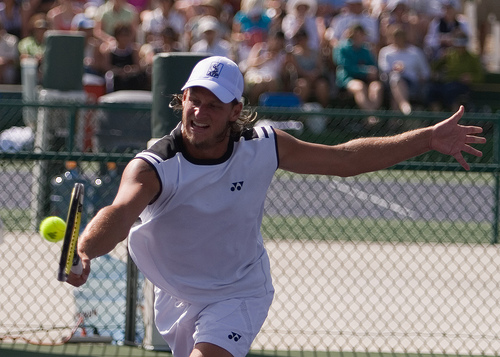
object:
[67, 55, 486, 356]
man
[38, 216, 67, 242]
ball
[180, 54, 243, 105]
cap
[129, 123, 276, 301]
shirt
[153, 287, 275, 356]
shorts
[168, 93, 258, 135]
hair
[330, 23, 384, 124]
person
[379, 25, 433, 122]
person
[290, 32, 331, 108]
person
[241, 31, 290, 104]
person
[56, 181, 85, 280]
racket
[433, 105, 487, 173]
hand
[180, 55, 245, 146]
head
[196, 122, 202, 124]
teeth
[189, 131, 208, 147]
chin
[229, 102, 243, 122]
ear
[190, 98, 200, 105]
eye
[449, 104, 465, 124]
thumb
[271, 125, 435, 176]
arm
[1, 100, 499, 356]
fence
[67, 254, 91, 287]
hand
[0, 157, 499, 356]
court